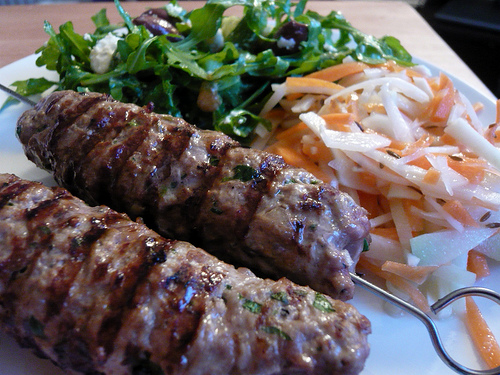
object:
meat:
[0, 82, 117, 165]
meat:
[0, 304, 81, 373]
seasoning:
[242, 291, 333, 340]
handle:
[429, 285, 499, 374]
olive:
[132, 5, 183, 35]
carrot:
[284, 74, 342, 95]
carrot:
[308, 60, 368, 81]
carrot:
[274, 111, 353, 141]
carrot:
[421, 70, 456, 126]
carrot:
[441, 196, 474, 225]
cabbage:
[322, 76, 428, 103]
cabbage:
[378, 82, 412, 146]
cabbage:
[444, 116, 499, 171]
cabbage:
[329, 155, 377, 193]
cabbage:
[410, 227, 499, 268]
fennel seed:
[423, 122, 439, 132]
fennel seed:
[446, 154, 467, 164]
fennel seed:
[383, 149, 403, 159]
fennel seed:
[436, 198, 449, 208]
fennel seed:
[476, 209, 494, 223]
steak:
[0, 330, 377, 373]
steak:
[196, 152, 256, 226]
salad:
[1, 0, 300, 129]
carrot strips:
[459, 82, 498, 137]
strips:
[393, 66, 459, 92]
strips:
[298, 118, 394, 155]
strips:
[243, 25, 310, 79]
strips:
[131, 32, 254, 82]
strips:
[257, 77, 328, 127]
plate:
[22, 12, 484, 359]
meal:
[23, 3, 484, 370]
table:
[11, 2, 86, 52]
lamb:
[43, 96, 337, 293]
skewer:
[356, 269, 499, 374]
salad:
[237, 51, 465, 222]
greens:
[94, 19, 303, 101]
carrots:
[388, 184, 430, 231]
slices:
[340, 104, 389, 161]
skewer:
[0, 58, 448, 372]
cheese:
[78, 22, 162, 88]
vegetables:
[205, 88, 256, 135]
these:
[88, 15, 238, 97]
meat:
[318, 237, 371, 290]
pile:
[297, 17, 376, 65]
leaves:
[171, 6, 218, 54]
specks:
[226, 284, 275, 330]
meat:
[80, 108, 120, 132]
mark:
[73, 190, 167, 323]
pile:
[88, 57, 110, 76]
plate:
[0, 37, 54, 178]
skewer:
[0, 77, 35, 110]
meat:
[20, 109, 55, 167]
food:
[28, 10, 480, 305]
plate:
[1, 31, 467, 364]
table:
[330, 0, 473, 51]